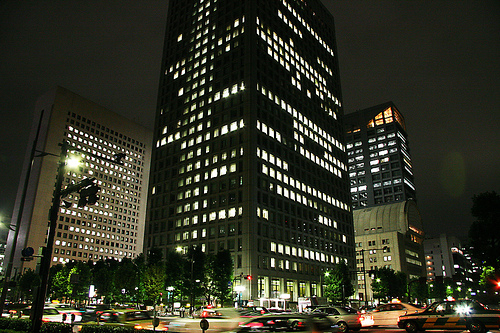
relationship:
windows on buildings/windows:
[139, 1, 346, 281] [0, 0, 485, 309]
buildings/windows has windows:
[0, 0, 485, 309] [139, 1, 346, 281]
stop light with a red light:
[244, 272, 254, 282] [247, 275, 252, 279]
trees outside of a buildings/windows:
[6, 241, 248, 318] [0, 0, 485, 309]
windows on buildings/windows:
[216, 85, 271, 145] [0, 0, 485, 309]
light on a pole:
[62, 150, 91, 178] [12, 114, 145, 328]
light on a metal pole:
[62, 150, 91, 178] [36, 178, 73, 325]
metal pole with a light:
[36, 128, 99, 325] [65, 156, 82, 172]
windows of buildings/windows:
[139, 1, 346, 281] [0, 0, 485, 309]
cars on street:
[79, 302, 499, 331] [11, 314, 484, 331]